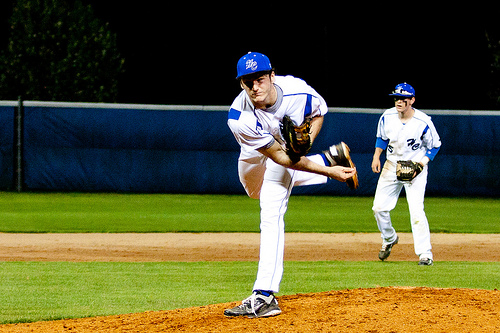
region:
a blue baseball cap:
[236, 51, 291, 81]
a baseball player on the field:
[130, 51, 358, 325]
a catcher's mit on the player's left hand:
[271, 111, 312, 157]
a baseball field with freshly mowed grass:
[26, 187, 491, 322]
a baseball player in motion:
[370, 65, 440, 275]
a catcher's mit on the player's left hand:
[395, 150, 427, 190]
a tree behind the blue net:
[1, 2, 129, 100]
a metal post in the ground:
[15, 93, 32, 199]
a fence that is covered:
[26, 97, 496, 197]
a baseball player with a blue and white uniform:
[361, 76, 450, 273]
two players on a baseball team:
[10, 4, 461, 309]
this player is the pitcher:
[179, 49, 359, 316]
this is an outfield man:
[362, 65, 451, 277]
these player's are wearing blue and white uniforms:
[198, 42, 450, 249]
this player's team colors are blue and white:
[195, 48, 360, 310]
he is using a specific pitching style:
[179, 48, 366, 284]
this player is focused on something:
[362, 71, 461, 270]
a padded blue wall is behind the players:
[13, 34, 487, 201]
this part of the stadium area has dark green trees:
[0, 5, 498, 97]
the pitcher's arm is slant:
[240, 124, 359, 184]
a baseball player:
[214, 48, 341, 165]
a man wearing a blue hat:
[223, 50, 317, 139]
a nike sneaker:
[221, 281, 290, 328]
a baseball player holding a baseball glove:
[208, 45, 351, 195]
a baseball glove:
[273, 108, 313, 151]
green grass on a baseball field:
[53, 173, 415, 253]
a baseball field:
[41, 154, 491, 329]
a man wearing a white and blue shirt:
[198, 46, 323, 170]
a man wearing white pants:
[365, 66, 477, 301]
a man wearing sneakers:
[354, 66, 455, 320]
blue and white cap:
[235, 51, 272, 80]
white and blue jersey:
[228, 75, 328, 155]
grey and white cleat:
[223, 293, 282, 315]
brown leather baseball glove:
[279, 115, 311, 160]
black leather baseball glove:
[397, 159, 420, 181]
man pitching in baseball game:
[223, 51, 357, 319]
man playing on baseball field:
[373, 83, 442, 267]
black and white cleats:
[374, 235, 434, 267]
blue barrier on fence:
[1, 101, 498, 198]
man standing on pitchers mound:
[225, 51, 358, 316]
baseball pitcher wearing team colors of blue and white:
[193, 42, 365, 326]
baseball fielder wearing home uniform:
[355, 67, 467, 284]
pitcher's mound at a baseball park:
[9, 274, 487, 329]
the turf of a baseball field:
[7, 168, 482, 322]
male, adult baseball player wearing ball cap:
[221, 47, 286, 109]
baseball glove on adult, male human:
[386, 155, 428, 190]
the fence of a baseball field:
[3, 65, 488, 212]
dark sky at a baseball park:
[13, 15, 448, 180]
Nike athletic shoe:
[203, 280, 298, 323]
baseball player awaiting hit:
[381, 74, 423, 120]